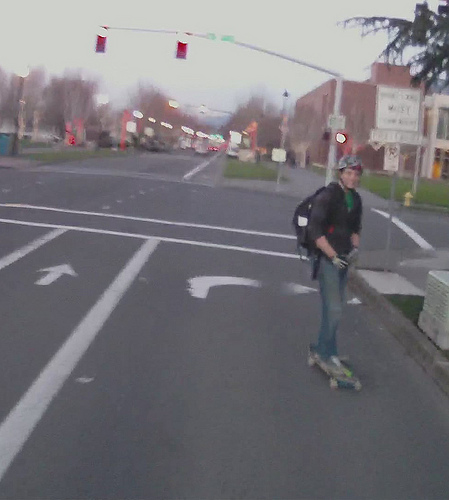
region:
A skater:
[303, 156, 350, 318]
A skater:
[288, 201, 351, 358]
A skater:
[305, 253, 362, 432]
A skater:
[330, 139, 355, 378]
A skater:
[308, 203, 374, 353]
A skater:
[321, 220, 357, 402]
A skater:
[339, 175, 393, 405]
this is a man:
[287, 155, 381, 344]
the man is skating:
[289, 151, 377, 370]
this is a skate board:
[322, 366, 357, 392]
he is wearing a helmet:
[337, 156, 362, 168]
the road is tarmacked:
[245, 406, 355, 493]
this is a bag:
[290, 195, 308, 246]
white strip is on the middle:
[56, 282, 141, 371]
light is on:
[332, 125, 350, 143]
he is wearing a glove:
[334, 250, 350, 267]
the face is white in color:
[346, 173, 355, 185]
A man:
[294, 172, 378, 476]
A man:
[269, 199, 357, 427]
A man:
[287, 187, 331, 332]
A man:
[315, 214, 405, 419]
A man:
[299, 182, 365, 301]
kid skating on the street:
[247, 139, 406, 410]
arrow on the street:
[22, 255, 96, 319]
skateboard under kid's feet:
[292, 328, 371, 406]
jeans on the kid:
[310, 264, 365, 339]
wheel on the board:
[347, 372, 370, 404]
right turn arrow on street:
[184, 268, 311, 337]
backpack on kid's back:
[260, 183, 328, 270]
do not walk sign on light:
[322, 119, 352, 158]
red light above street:
[152, 10, 218, 83]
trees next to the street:
[42, 64, 108, 128]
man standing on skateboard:
[286, 145, 386, 403]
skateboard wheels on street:
[305, 355, 342, 394]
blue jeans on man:
[309, 251, 352, 361]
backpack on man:
[283, 181, 324, 263]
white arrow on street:
[30, 245, 88, 304]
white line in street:
[81, 239, 157, 357]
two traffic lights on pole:
[82, 23, 198, 74]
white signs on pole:
[365, 81, 432, 198]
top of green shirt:
[341, 186, 353, 218]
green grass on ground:
[229, 159, 273, 189]